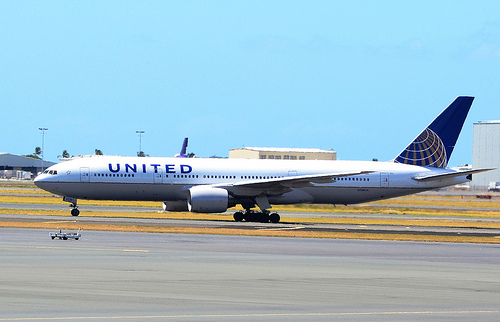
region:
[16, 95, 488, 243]
Passenger jet on the runway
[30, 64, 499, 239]
Passenger jet on the runway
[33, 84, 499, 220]
Passenger jet on the runway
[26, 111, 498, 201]
Passenger jet on the runway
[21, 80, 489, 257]
Passenger jet on the runway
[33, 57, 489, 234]
Passenger jet on the runway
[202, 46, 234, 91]
white clouds in blue sky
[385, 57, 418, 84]
white clouds in blue sky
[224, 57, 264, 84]
white clouds in blue sky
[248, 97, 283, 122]
white clouds in blue sky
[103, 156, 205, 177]
United is the name on the side of the Airplane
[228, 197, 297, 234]
Jets is resting on its wheels on the ground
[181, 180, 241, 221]
Large jet engine mounted on the wing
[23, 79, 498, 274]
Large airplane is ready for its takeoff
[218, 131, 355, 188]
Large Airplane hangar is seen in the background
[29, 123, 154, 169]
Light posts sit above the large buildings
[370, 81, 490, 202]
Tail on plane is covered in blue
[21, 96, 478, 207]
blue and white plane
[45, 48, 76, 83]
white clouds in blue sky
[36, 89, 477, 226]
white and blue plane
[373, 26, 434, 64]
white clouds in blue sky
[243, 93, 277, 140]
white clouds in blue sky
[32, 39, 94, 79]
white clouds in blue sky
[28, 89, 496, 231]
plane at an airport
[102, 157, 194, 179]
word on the side of the plane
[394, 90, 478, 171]
blue vertical tail of the plane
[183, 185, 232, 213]
engine under the left wing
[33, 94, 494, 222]
plane on the runway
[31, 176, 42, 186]
nose of a plane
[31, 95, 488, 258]
A United Airlines jet on a tarmac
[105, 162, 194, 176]
Blue lettering on a jet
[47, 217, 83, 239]
A cart on a tarmac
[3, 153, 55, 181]
A small building behind a jet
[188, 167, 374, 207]
The left wing of a plane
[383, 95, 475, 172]
The tail of a jet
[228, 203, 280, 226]
Wheels on the bottom of a jet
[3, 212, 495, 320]
A runway for airplanes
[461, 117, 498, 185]
A tall gray building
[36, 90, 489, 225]
Blue and white airplane on the runway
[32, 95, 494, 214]
Blue and white airplane on the runway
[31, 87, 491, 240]
Blue and white airplane on the runway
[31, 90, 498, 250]
Blue and white airplane on the runway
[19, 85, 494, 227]
Blue and white airplane on the runway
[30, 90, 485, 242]
Blue and white airplane on the runway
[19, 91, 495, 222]
Blue and white airplane on the runway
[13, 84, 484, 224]
Blue and white airplane on the runway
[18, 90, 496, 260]
Blue and white airplane on the runway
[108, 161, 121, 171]
the letter U is blue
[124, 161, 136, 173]
the letter N is blue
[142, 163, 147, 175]
the letter I is blue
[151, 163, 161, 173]
the letter T is blue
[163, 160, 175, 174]
the letter E is blue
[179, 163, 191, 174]
the letter D is blue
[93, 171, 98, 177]
the airplane window is small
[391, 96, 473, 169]
the tail is dark blue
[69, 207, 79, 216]
the wheel is black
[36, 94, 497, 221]
the plane is blue and white